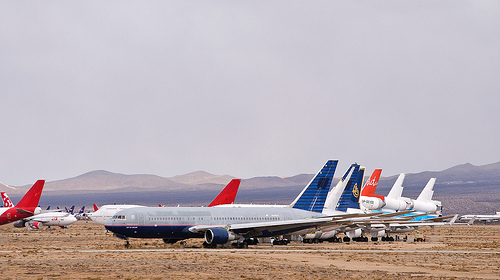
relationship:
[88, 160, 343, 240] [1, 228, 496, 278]
plane in desert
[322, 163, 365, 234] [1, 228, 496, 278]
plane in desert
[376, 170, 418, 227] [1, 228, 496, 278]
plane in desert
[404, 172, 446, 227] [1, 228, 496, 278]
plane in desert